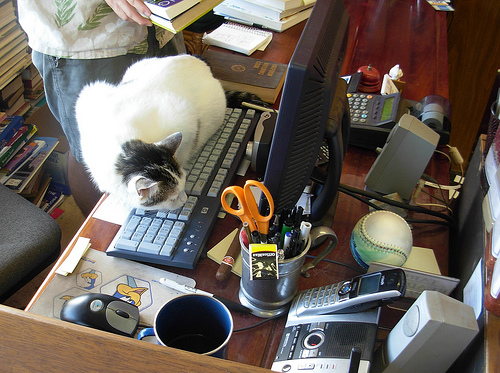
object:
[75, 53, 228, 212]
cat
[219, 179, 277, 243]
scissors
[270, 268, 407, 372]
phone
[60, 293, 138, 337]
mouse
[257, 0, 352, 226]
computer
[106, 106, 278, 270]
keyboard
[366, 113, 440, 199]
speaker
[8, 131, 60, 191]
books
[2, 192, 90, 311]
floor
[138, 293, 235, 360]
cup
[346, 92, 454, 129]
calculator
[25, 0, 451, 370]
desk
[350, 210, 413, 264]
ball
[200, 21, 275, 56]
notebook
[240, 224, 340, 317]
mug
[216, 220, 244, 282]
cigar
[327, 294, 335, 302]
buttons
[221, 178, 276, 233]
handles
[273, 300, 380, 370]
base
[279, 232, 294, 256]
pens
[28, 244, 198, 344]
mouse pad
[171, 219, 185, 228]
number pad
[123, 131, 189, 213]
head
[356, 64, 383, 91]
bell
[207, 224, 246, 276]
pad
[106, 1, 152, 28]
hand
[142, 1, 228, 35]
books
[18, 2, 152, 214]
person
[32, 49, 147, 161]
pants